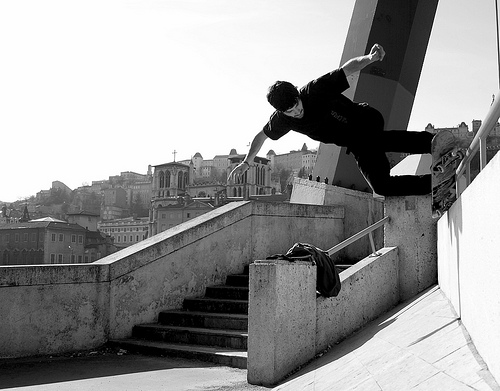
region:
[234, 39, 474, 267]
man on skateboard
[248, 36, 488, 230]
man in black shirt and pants on skateboard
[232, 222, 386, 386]
black sweater laying on hand rail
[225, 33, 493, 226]
man balancing on rail with skateboard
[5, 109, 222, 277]
old buildings in skyline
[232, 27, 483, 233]
man doing skateboard trick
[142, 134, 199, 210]
old church building with cross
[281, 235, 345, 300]
clothes hanging over a rail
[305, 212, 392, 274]
metal rail near the stairs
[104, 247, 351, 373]
stairs leading down to the surface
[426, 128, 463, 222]
skateboard in the air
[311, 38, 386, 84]
left hand in the air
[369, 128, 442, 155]
left leg of the man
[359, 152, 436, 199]
right leg of the man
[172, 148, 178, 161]
cross on a building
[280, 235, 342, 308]
jacket is on the rail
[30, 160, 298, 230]
city behind the steps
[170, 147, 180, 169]
cross above the building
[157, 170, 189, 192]
arches in the building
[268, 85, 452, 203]
man on the skateboard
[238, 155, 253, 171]
watch on the wrist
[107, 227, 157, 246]
windows on the buildings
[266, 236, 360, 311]
A jacket on the railing.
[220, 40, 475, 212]
A man on a skateboard.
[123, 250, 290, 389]
A set of stairs.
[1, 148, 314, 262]
Many buildings behind the stairs.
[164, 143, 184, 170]
A cross on top of the building.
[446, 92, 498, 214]
The railing on the wall.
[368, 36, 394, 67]
A hand on the man.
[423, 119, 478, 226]
A skateboard sliding on the railing.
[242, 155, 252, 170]
A watch on the man's wrist.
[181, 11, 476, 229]
this is a man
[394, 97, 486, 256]
this is a skateboard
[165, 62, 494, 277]
man on a skateboard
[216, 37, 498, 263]
man is doing a trick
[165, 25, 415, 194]
man has arms extended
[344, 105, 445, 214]
man wearing dark pants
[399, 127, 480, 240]
graffiti on bottom of skateboard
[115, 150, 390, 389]
a set of stairs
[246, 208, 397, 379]
clothes draped on rail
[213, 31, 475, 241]
Person doing a trick